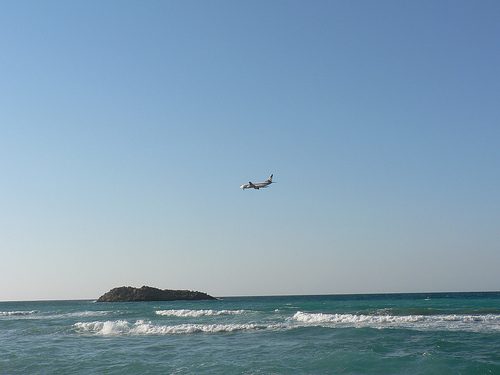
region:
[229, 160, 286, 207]
The airplane is flying.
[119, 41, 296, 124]
The sky is blue.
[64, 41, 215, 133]
The sky is clear.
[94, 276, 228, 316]
The island is next to the ocean.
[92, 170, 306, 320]
The airplane is landing on the island.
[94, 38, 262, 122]
No clouds are in the sky.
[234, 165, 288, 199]
The airplane's nose is pointing to the left.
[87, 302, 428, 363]
The ocean has waves.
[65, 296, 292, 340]
The waves are smooth.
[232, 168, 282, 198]
The plane is small.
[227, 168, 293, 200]
the plane in the sky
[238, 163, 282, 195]
the plane is flying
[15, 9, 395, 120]
the sky is blue and clear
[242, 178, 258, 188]
the wing of the plane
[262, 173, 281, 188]
the tail of the plane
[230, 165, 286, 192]
the plane flying over the ocean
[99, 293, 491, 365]
waves in the ocean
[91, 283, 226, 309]
the island in the ocean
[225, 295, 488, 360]
the water is calm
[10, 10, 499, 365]
the weather is good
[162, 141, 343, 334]
a plane flying over the ocean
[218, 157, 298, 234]
a plane flying in the sky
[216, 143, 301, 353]
a plane flying over water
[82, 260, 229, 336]
a island in the middle of water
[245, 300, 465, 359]
white waves in the water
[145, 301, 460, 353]
white waves in the ocean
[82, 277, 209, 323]
a island covered with trees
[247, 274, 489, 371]
the blue and green water of the ocean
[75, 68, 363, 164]
a clear blue sky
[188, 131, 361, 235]
a plane flying in a blue sky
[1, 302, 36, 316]
The wave on the left side of the ocean.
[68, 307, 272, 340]
The waves in the middle of the ocean.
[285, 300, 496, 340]
The waves on the right side of the ocean.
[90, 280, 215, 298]
The island in the middle of the ocean.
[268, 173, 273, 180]
The tail of the plane.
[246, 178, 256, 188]
The sidewing of the plane.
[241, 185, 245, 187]
The nose of the plane.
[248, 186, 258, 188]
The wheels under the plane.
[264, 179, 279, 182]
The wings near the tail of the plane.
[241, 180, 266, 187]
The body of the plane.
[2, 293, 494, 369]
turquoise sea with lines of low waves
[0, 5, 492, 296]
clear blue sky over sea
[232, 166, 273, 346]
silver airplane flying over the sea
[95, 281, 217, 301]
rocky island in the ocean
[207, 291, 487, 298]
darker edge of the horizon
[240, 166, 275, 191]
dark wings across bottom of plane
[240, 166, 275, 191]
tail curving upward on back of plane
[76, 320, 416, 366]
calm water in front of waves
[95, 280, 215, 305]
curved and angled edge over island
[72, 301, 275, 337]
shorter wave in back of longer wave